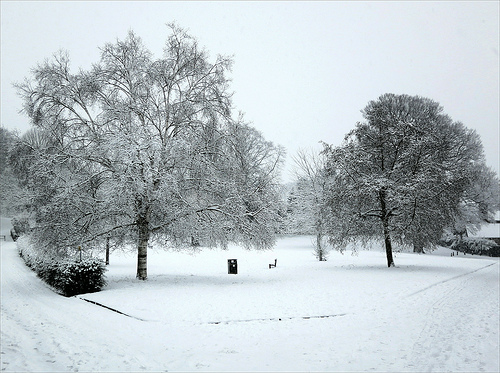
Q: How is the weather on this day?
A: It is cloudy.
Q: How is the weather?
A: It is cloudy.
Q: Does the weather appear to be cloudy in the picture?
A: Yes, it is cloudy.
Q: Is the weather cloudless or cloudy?
A: It is cloudy.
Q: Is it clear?
A: No, it is cloudy.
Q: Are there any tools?
A: No, there are no tools.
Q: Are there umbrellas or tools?
A: No, there are no tools or umbrellas.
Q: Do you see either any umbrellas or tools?
A: No, there are no tools or umbrellas.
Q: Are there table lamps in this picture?
A: No, there are no table lamps.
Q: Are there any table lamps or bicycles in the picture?
A: No, there are no table lamps or bicycles.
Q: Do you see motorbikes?
A: No, there are no motorbikes.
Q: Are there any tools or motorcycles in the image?
A: No, there are no motorcycles or tools.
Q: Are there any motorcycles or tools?
A: No, there are no motorcycles or tools.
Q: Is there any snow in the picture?
A: Yes, there is snow.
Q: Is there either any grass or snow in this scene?
A: Yes, there is snow.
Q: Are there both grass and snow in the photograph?
A: No, there is snow but no grass.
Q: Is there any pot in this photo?
A: No, there are no pots.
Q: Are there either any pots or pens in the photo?
A: No, there are no pots or pens.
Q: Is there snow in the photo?
A: Yes, there is snow.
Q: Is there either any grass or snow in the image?
A: Yes, there is snow.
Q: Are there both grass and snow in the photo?
A: No, there is snow but no grass.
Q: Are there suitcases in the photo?
A: No, there are no suitcases.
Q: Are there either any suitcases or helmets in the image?
A: No, there are no suitcases or helmets.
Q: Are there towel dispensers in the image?
A: No, there are no towel dispensers.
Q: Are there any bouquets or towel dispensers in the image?
A: No, there are no towel dispensers or bouquets.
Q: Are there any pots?
A: No, there are no pots.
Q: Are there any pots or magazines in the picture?
A: No, there are no pots or magazines.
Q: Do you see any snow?
A: Yes, there is snow.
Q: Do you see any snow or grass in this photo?
A: Yes, there is snow.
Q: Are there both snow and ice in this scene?
A: No, there is snow but no ice.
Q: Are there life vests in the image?
A: No, there are no life vests.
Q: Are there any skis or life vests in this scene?
A: No, there are no life vests or skis.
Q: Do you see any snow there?
A: Yes, there is snow.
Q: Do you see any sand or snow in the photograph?
A: Yes, there is snow.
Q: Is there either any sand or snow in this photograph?
A: Yes, there is snow.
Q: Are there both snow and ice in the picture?
A: No, there is snow but no ice.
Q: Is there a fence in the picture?
A: No, there are no fences.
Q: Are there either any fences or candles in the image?
A: No, there are no fences or candles.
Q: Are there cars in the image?
A: No, there are no cars.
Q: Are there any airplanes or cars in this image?
A: No, there are no cars or airplanes.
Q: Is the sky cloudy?
A: Yes, the sky is cloudy.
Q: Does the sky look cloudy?
A: Yes, the sky is cloudy.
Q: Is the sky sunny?
A: No, the sky is cloudy.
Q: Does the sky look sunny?
A: No, the sky is cloudy.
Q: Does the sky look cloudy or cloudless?
A: The sky is cloudy.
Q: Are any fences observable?
A: No, there are no fences.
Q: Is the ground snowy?
A: Yes, the ground is snowy.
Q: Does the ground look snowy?
A: Yes, the ground is snowy.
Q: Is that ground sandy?
A: No, the ground is snowy.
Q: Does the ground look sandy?
A: No, the ground is snowy.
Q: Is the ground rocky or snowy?
A: The ground is snowy.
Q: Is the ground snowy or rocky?
A: The ground is snowy.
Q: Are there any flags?
A: No, there are no flags.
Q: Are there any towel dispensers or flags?
A: No, there are no flags or towel dispensers.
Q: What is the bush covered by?
A: The bush is covered by the snow.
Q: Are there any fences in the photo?
A: No, there are no fences.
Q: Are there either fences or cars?
A: No, there are no fences or cars.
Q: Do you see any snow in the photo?
A: Yes, there is snow.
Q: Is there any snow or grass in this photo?
A: Yes, there is snow.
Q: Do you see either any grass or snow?
A: Yes, there is snow.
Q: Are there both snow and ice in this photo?
A: No, there is snow but no ice.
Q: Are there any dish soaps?
A: No, there are no dish soaps.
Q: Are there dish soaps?
A: No, there are no dish soaps.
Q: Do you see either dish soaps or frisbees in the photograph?
A: No, there are no dish soaps or frisbees.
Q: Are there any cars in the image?
A: No, there are no cars.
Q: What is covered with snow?
A: The tree is covered with snow.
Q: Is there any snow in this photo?
A: Yes, there is snow.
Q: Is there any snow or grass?
A: Yes, there is snow.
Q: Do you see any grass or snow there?
A: Yes, there is snow.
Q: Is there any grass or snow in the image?
A: Yes, there is snow.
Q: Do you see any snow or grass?
A: Yes, there is snow.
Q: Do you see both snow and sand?
A: No, there is snow but no sand.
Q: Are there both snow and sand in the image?
A: No, there is snow but no sand.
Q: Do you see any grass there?
A: No, there is no grass.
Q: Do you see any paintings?
A: No, there are no paintings.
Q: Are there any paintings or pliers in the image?
A: No, there are no paintings or pliers.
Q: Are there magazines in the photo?
A: No, there are no magazines.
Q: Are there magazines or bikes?
A: No, there are no magazines or bikes.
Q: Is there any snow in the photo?
A: Yes, there is snow.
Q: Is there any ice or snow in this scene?
A: Yes, there is snow.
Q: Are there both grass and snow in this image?
A: No, there is snow but no grass.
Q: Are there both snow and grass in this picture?
A: No, there is snow but no grass.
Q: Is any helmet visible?
A: No, there are no helmets.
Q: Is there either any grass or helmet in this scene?
A: No, there are no helmets or grass.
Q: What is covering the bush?
A: The snow is covering the bush.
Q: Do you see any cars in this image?
A: No, there are no cars.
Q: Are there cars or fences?
A: No, there are no cars or fences.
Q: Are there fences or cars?
A: No, there are no cars or fences.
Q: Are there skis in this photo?
A: No, there are no skis.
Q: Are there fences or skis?
A: No, there are no skis or fences.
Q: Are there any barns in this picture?
A: No, there are no barns.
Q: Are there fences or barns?
A: No, there are no barns or fences.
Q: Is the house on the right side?
A: Yes, the house is on the right of the image.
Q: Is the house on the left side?
A: No, the house is on the right of the image.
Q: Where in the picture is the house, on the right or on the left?
A: The house is on the right of the image.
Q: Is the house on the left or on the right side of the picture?
A: The house is on the right of the image.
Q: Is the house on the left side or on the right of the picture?
A: The house is on the right of the image.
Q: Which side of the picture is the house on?
A: The house is on the right of the image.